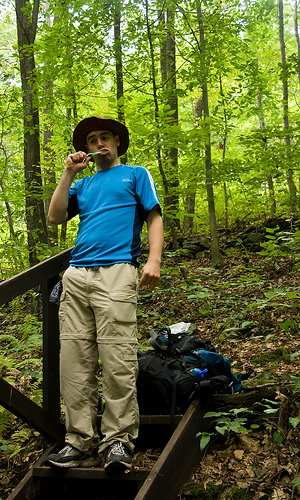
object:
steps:
[47, 405, 122, 494]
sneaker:
[42, 435, 102, 468]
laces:
[60, 445, 71, 457]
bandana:
[49, 281, 63, 306]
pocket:
[129, 265, 138, 285]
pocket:
[62, 265, 72, 284]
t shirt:
[67, 165, 157, 268]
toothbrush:
[78, 151, 105, 163]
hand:
[66, 150, 91, 171]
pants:
[58, 262, 145, 459]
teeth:
[98, 147, 113, 158]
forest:
[0, 0, 300, 304]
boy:
[47, 116, 164, 471]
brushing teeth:
[82, 148, 109, 164]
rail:
[7, 398, 199, 500]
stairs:
[5, 378, 212, 499]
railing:
[0, 244, 75, 445]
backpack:
[136, 327, 238, 415]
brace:
[0, 374, 57, 439]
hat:
[73, 116, 129, 163]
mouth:
[98, 147, 108, 154]